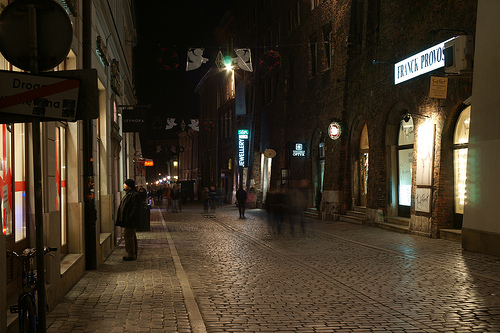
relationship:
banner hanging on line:
[231, 42, 259, 73] [133, 32, 319, 55]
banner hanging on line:
[184, 46, 204, 72] [133, 32, 319, 55]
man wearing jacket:
[111, 179, 153, 256] [116, 188, 143, 225]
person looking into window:
[114, 174, 143, 261] [99, 145, 108, 192]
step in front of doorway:
[339, 211, 363, 224] [338, 89, 454, 235]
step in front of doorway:
[343, 207, 367, 217] [338, 89, 454, 235]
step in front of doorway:
[354, 200, 379, 210] [338, 89, 454, 235]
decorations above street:
[235, 50, 256, 79] [0, 202, 500, 333]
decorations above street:
[160, 111, 176, 132] [0, 202, 500, 333]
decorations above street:
[189, 113, 201, 131] [0, 202, 500, 333]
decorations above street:
[179, 38, 258, 82] [0, 202, 500, 333]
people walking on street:
[263, 176, 310, 236] [0, 202, 500, 333]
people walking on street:
[284, 186, 314, 235] [0, 202, 500, 333]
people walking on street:
[113, 171, 147, 265] [0, 202, 500, 333]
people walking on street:
[233, 182, 249, 220] [0, 202, 500, 333]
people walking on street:
[197, 177, 215, 217] [0, 202, 500, 333]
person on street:
[83, 172, 172, 281] [168, 189, 391, 331]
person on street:
[235, 186, 251, 222] [168, 189, 391, 331]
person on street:
[287, 173, 316, 234] [168, 189, 391, 331]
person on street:
[258, 170, 288, 233] [168, 189, 391, 331]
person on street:
[197, 175, 215, 218] [168, 189, 391, 331]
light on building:
[411, 116, 434, 163] [265, 3, 464, 239]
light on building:
[327, 120, 344, 141] [265, 3, 464, 239]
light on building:
[169, 159, 178, 169] [171, 119, 203, 209]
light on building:
[218, 53, 235, 73] [214, 97, 237, 203]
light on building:
[265, 145, 277, 177] [213, 56, 250, 202]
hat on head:
[121, 176, 138, 186] [120, 177, 141, 191]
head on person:
[120, 177, 141, 191] [113, 171, 156, 267]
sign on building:
[0, 62, 110, 125] [0, 0, 92, 330]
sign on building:
[0, 0, 76, 70] [0, 0, 92, 330]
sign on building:
[387, 33, 456, 87] [289, 4, 478, 236]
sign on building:
[427, 73, 454, 96] [289, 4, 478, 236]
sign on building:
[327, 119, 343, 142] [289, 4, 478, 236]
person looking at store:
[116, 175, 151, 265] [78, 0, 123, 270]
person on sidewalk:
[113, 180, 152, 270] [110, 262, 167, 332]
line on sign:
[3, 82, 75, 99] [3, 73, 76, 119]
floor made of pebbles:
[172, 226, 499, 330] [445, 309, 460, 321]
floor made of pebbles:
[172, 226, 499, 330] [296, 323, 314, 330]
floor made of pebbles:
[172, 226, 499, 330] [384, 326, 402, 330]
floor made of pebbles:
[172, 226, 499, 330] [431, 311, 442, 323]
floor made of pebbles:
[172, 226, 499, 330] [387, 290, 407, 298]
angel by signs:
[187, 50, 201, 73] [236, 120, 252, 138]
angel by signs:
[226, 44, 256, 76] [236, 120, 252, 138]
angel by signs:
[160, 112, 174, 134] [236, 120, 252, 138]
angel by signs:
[183, 113, 200, 134] [236, 120, 252, 138]